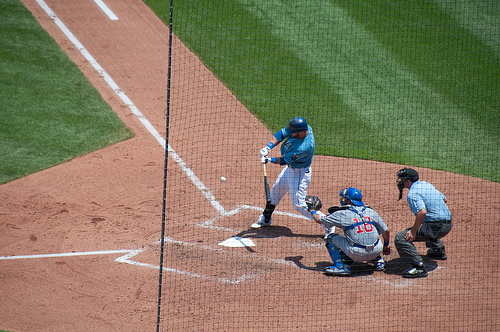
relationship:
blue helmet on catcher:
[345, 185, 361, 201] [345, 189, 363, 206]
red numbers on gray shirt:
[349, 215, 381, 235] [356, 219, 373, 232]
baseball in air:
[218, 175, 228, 184] [214, 171, 231, 187]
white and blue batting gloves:
[249, 136, 271, 169] [256, 141, 277, 168]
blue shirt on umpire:
[406, 183, 447, 227] [400, 169, 463, 318]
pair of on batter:
[267, 165, 325, 220] [245, 82, 323, 269]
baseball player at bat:
[245, 82, 323, 269] [255, 122, 325, 232]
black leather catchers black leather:
[302, 184, 322, 216] [302, 195, 322, 213]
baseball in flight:
[218, 175, 228, 184] [196, 113, 268, 269]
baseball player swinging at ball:
[245, 82, 323, 269] [196, 113, 268, 269]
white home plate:
[225, 222, 297, 250] [219, 224, 243, 273]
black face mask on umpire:
[399, 168, 412, 192] [400, 169, 463, 318]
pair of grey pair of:
[319, 225, 417, 294] [322, 232, 387, 268]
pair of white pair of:
[262, 152, 328, 240] [322, 232, 387, 268]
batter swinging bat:
[245, 82, 323, 269] [255, 122, 325, 232]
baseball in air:
[198, 158, 250, 211] [214, 171, 231, 187]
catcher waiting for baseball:
[345, 189, 363, 206] [218, 175, 228, 184]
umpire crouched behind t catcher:
[400, 169, 463, 318] [345, 189, 363, 206]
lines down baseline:
[32, 0, 168, 149] [84, 64, 240, 199]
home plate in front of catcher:
[210, 207, 263, 274] [345, 189, 363, 206]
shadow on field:
[251, 201, 308, 273] [0, 1, 499, 332]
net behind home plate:
[237, 31, 491, 104] [210, 207, 263, 274]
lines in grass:
[251, 36, 475, 58] [237, 31, 491, 104]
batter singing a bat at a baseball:
[248, 114, 327, 233] [218, 175, 228, 184]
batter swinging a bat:
[248, 114, 327, 233] [255, 122, 325, 232]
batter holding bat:
[248, 114, 327, 233] [255, 122, 325, 232]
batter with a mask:
[248, 114, 327, 233] [332, 181, 371, 224]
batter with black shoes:
[248, 114, 327, 233] [399, 216, 447, 289]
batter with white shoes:
[248, 114, 327, 233] [244, 207, 313, 238]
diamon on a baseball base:
[210, 207, 263, 274] [194, 192, 278, 309]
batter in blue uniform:
[248, 114, 327, 233] [232, 79, 377, 295]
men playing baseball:
[232, 79, 377, 295] [198, 158, 250, 211]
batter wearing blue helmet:
[245, 110, 328, 236] [279, 114, 314, 133]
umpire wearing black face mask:
[393, 166, 455, 279] [399, 168, 412, 192]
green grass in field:
[16, 33, 80, 155] [6, 3, 496, 324]